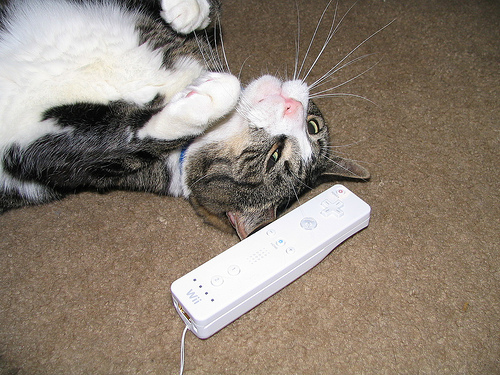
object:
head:
[181, 58, 382, 240]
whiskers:
[194, 0, 388, 126]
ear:
[320, 153, 371, 178]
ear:
[226, 204, 278, 241]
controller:
[170, 184, 371, 375]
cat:
[0, 0, 397, 240]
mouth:
[259, 77, 293, 103]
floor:
[96, 97, 500, 372]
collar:
[178, 139, 193, 195]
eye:
[307, 118, 319, 135]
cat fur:
[10, 22, 206, 156]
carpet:
[0, 0, 499, 375]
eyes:
[266, 147, 281, 173]